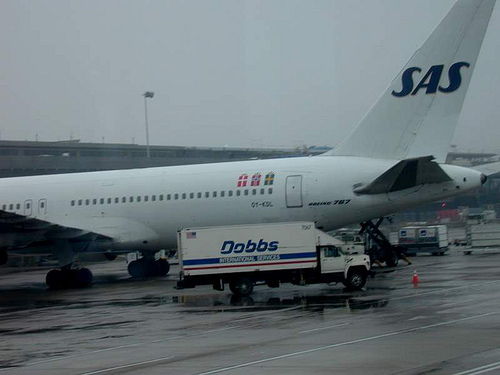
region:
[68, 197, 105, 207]
five windows on airplane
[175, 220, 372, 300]
white truck with blue and red stripes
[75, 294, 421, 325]
puddles from rain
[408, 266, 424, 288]
orange cone with white stripes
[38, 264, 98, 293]
airplane landing gear wheels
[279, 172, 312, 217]
door of airplane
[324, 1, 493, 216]
tail of airplane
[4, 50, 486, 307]
large jet and truck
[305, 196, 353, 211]
boeing 787 emblem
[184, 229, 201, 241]
inverted American flag painted on truck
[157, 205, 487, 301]
Truck on the tarmac.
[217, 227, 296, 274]
Blue writing on the truck.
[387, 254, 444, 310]
Orange cone on the tarmac.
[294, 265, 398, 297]
Tires on the truck.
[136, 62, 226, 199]
Light pole behind the plane.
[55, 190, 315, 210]
Windows on the plane.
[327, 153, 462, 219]
Wings on the plane.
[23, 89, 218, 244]
Buildings behind the plane.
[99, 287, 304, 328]
Water on the runway.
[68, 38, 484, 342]
Plane on the runway.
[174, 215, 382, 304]
white dobbs truck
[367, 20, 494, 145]
blue SAS logo on plane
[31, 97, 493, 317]
white airplane with flag logos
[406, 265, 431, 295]
white and orange traffic cone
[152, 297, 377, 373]
rain on concrete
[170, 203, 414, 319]
white truck with blue text and red stripe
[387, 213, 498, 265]
two white boxes with blue squares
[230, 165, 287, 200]
international flags above plane windows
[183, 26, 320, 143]
grey cloudy sky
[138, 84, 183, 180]
grey lamp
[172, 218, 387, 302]
a cargo tuck at the airport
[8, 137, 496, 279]
a plane being loaded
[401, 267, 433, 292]
a person wearing a red shirt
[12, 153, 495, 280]
a stationary plane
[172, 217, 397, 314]
a white truck with blue and red strips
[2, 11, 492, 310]
an SAS passenger train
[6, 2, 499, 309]
a ruck and an aeroplane on the airport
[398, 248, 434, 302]
a lady in a red dress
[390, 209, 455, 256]
a cargo truck in the background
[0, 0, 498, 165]
clear sky on the background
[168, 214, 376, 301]
Truck with Dobbs written on the side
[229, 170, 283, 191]
Three presents on the side of the plane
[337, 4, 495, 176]
Back wing of plane reading sas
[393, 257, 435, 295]
orange cone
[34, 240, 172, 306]
Front two landing wheel apparatuses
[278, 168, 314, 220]
emergency door on plane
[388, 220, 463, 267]
Luggage carrier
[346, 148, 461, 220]
Back horizontal wing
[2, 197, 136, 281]
Front horizontal wing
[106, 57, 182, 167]
Lamp pole on building